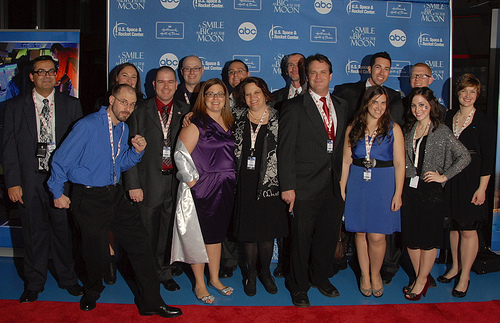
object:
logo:
[237, 21, 258, 42]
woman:
[338, 86, 404, 297]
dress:
[341, 120, 401, 234]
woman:
[176, 77, 235, 304]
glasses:
[205, 91, 226, 98]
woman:
[444, 73, 493, 303]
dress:
[445, 106, 494, 232]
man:
[46, 84, 183, 318]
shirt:
[47, 106, 145, 199]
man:
[2, 54, 89, 304]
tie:
[38, 98, 55, 172]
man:
[277, 53, 348, 307]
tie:
[319, 97, 336, 142]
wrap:
[168, 135, 211, 271]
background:
[105, 0, 453, 109]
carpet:
[2, 299, 500, 323]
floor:
[2, 255, 500, 303]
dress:
[187, 112, 237, 245]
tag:
[113, 173, 117, 186]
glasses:
[113, 94, 137, 108]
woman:
[399, 86, 474, 304]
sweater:
[402, 119, 472, 187]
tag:
[363, 168, 372, 181]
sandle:
[359, 276, 372, 297]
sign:
[2, 28, 81, 260]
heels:
[402, 275, 430, 300]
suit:
[0, 85, 84, 294]